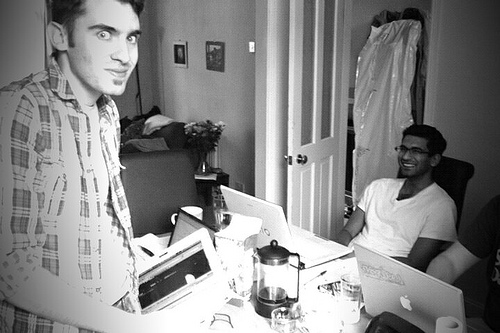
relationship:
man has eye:
[6, 12, 183, 279] [93, 32, 146, 49]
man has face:
[6, 12, 183, 279] [70, 22, 149, 110]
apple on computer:
[386, 293, 410, 317] [339, 232, 473, 333]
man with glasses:
[6, 12, 183, 279] [399, 140, 443, 165]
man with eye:
[6, 12, 183, 279] [93, 32, 146, 49]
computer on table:
[339, 232, 473, 333] [92, 184, 351, 332]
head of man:
[80, 11, 121, 38] [6, 12, 183, 279]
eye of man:
[93, 32, 146, 49] [6, 12, 183, 279]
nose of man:
[101, 46, 141, 70] [6, 12, 183, 279]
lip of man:
[104, 53, 147, 78] [6, 12, 183, 279]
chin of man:
[79, 76, 140, 113] [6, 12, 183, 279]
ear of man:
[40, 24, 91, 63] [6, 12, 183, 279]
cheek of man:
[98, 46, 127, 85] [6, 12, 183, 279]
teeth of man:
[105, 63, 136, 84] [6, 12, 183, 279]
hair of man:
[57, 3, 81, 20] [6, 12, 183, 279]